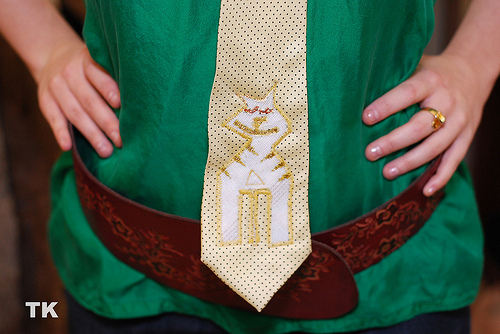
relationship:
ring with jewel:
[421, 105, 448, 126] [428, 113, 451, 127]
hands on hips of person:
[2, 4, 498, 329] [17, 38, 486, 203]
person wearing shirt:
[2, 1, 482, 328] [50, 3, 486, 318]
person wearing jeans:
[2, 1, 482, 328] [66, 284, 473, 331]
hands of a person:
[21, 38, 137, 160] [2, 1, 482, 328]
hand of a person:
[361, 50, 484, 198] [2, 1, 482, 328]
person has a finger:
[2, 1, 482, 328] [364, 70, 436, 123]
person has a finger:
[2, 1, 482, 328] [364, 105, 446, 159]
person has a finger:
[2, 1, 482, 328] [424, 133, 473, 194]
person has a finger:
[2, 1, 482, 328] [84, 57, 124, 107]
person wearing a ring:
[2, 1, 499, 332] [418, 106, 447, 127]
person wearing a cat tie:
[2, 1, 499, 332] [199, 0, 316, 314]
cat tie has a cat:
[199, 0, 316, 314] [218, 82, 293, 247]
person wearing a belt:
[2, 1, 499, 332] [69, 130, 447, 314]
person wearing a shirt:
[2, 1, 499, 332] [50, 3, 486, 318]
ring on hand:
[421, 105, 448, 126] [360, 50, 499, 196]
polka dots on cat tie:
[199, 0, 313, 313] [199, 0, 316, 314]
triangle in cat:
[243, 169, 267, 189] [218, 82, 293, 247]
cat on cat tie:
[218, 82, 293, 247] [199, 0, 316, 314]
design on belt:
[328, 198, 435, 272] [69, 130, 447, 314]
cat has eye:
[218, 82, 293, 247] [245, 106, 258, 115]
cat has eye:
[218, 82, 293, 247] [259, 104, 272, 115]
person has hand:
[2, 1, 482, 328] [360, 50, 499, 196]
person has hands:
[2, 1, 482, 328] [21, 38, 137, 160]